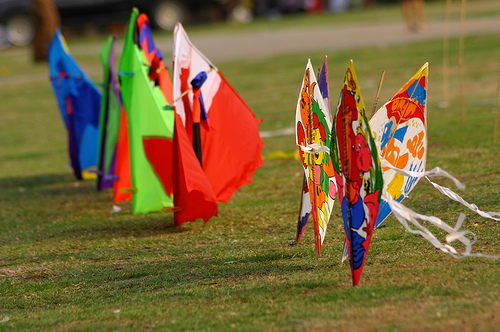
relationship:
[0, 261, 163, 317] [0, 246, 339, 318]
part of a shade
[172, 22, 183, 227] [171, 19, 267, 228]
edge of a flag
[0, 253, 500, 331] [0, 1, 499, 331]
part of a ground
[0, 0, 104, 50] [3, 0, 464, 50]
part of a stand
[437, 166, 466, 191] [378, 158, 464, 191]
part of a ribbon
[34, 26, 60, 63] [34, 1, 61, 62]
part of a stick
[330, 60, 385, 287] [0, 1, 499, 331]
kite on ground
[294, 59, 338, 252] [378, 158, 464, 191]
kite has ribbon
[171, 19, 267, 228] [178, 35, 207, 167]
flag has drawings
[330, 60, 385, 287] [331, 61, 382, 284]
kite has several colors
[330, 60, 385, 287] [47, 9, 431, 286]
kite in line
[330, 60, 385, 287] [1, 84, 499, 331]
kite in grass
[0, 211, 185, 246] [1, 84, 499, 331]
shadow on grass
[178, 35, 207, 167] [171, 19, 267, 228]
children in flag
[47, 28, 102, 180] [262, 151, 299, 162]
kite has tail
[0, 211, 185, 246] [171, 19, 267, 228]
shadow from kite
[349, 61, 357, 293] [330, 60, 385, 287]
stick of kite